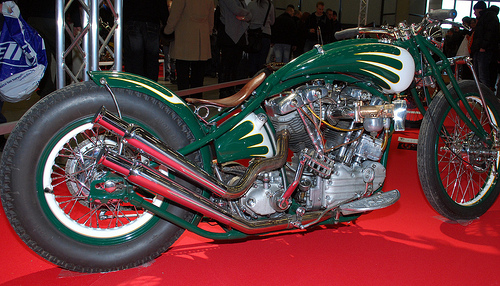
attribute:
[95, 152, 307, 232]
muffler — chrome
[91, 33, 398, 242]
motorcycle — old, on display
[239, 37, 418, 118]
tank — green, white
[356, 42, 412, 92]
design — white, yellow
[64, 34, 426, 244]
bike — green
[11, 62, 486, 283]
floor — red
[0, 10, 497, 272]
bike — metal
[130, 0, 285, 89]
people — in background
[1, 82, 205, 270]
tire — rear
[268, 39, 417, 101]
bike — painted, green, white, yellow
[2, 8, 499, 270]
green motorcycle — old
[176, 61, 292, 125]
seat — brown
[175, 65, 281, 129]
passenger site — brown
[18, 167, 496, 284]
carpet — red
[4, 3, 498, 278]
motorcycle — green, old, standing outside, on display, inside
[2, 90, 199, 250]
tire — black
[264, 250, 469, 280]
carpet — Red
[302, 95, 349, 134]
wires — red, yellow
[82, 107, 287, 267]
pipes — chrome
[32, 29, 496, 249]
bike — green, white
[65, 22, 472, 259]
motorcycle — green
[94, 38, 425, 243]
frame — steel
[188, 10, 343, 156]
people — gray-clothed, black-clothed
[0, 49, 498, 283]
platform — red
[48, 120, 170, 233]
wheel — green, white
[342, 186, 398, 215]
foot support — silver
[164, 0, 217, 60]
coat — beige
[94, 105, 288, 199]
muffler — chrome